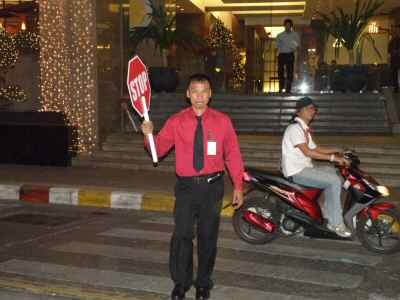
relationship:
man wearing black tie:
[137, 76, 245, 298] [192, 114, 205, 173]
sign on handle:
[126, 53, 158, 163] [141, 96, 159, 164]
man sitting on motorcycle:
[278, 94, 353, 240] [232, 144, 396, 254]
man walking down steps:
[137, 72, 245, 298] [6, 89, 398, 298]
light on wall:
[368, 21, 379, 35] [316, 14, 394, 64]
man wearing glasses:
[278, 96, 353, 238] [300, 103, 317, 113]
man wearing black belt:
[137, 76, 245, 298] [176, 170, 227, 183]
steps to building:
[70, 93, 400, 188] [34, 0, 396, 192]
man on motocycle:
[278, 94, 353, 240] [230, 146, 399, 256]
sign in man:
[101, 51, 171, 164] [137, 72, 245, 298]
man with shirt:
[137, 72, 245, 298] [172, 103, 270, 232]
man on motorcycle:
[278, 94, 353, 240] [232, 144, 396, 254]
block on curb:
[18, 184, 54, 208] [2, 178, 173, 211]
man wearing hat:
[278, 96, 353, 238] [284, 95, 316, 109]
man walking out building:
[272, 18, 302, 95] [34, 0, 396, 192]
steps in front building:
[89, 72, 398, 183] [214, 94, 392, 136]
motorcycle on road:
[237, 160, 399, 242] [0, 196, 399, 298]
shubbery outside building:
[0, 0, 100, 162] [3, 5, 397, 170]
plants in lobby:
[134, 1, 383, 94] [121, 10, 398, 92]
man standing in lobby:
[272, 16, 302, 94] [111, 2, 396, 98]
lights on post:
[43, 5, 99, 156] [39, 0, 97, 152]